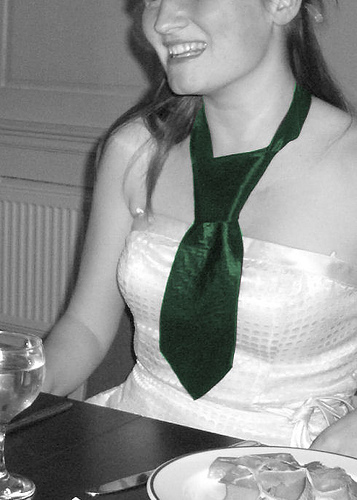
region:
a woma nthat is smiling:
[72, 9, 353, 218]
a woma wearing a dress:
[85, 195, 301, 387]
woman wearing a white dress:
[90, 209, 355, 473]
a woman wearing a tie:
[140, 199, 278, 411]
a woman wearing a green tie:
[159, 225, 325, 395]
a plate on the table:
[67, 403, 268, 496]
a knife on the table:
[87, 418, 212, 497]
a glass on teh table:
[10, 309, 101, 498]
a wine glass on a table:
[11, 324, 92, 489]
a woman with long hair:
[87, 34, 345, 287]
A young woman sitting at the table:
[0, 0, 352, 496]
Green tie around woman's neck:
[149, 70, 314, 403]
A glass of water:
[0, 321, 51, 494]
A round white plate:
[141, 439, 355, 497]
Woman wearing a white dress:
[73, 0, 351, 450]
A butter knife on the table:
[79, 432, 258, 494]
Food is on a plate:
[142, 437, 351, 494]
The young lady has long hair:
[85, 0, 351, 229]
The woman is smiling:
[112, 0, 333, 108]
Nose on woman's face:
[146, 0, 193, 36]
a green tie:
[184, 229, 231, 344]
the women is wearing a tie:
[162, 315, 223, 371]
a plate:
[174, 469, 196, 494]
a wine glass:
[2, 349, 38, 382]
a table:
[62, 426, 124, 461]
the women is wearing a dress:
[272, 295, 332, 376]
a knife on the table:
[107, 479, 136, 489]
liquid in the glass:
[7, 370, 29, 400]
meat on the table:
[212, 452, 303, 497]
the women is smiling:
[155, 36, 212, 64]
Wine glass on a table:
[0, 327, 66, 496]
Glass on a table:
[3, 320, 55, 496]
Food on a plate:
[203, 442, 347, 499]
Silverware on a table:
[73, 461, 176, 498]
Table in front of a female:
[8, 395, 213, 499]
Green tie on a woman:
[127, 100, 268, 405]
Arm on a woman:
[29, 107, 181, 396]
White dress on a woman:
[80, 175, 355, 442]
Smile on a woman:
[152, 33, 221, 65]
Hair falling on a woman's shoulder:
[99, 56, 203, 212]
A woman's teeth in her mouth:
[163, 33, 205, 63]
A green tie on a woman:
[188, 147, 252, 378]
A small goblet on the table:
[1, 331, 72, 474]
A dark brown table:
[70, 412, 163, 490]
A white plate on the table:
[173, 465, 218, 498]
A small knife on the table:
[73, 470, 110, 492]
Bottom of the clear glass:
[2, 473, 45, 490]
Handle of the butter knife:
[75, 491, 83, 498]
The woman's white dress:
[261, 278, 351, 383]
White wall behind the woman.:
[22, 191, 84, 273]